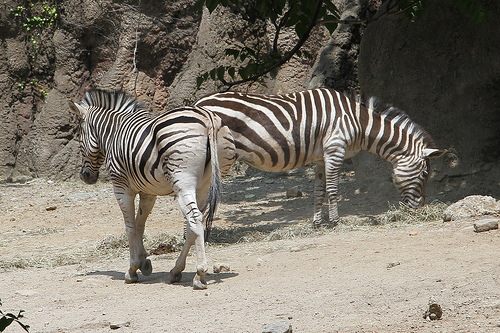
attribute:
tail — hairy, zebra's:
[181, 106, 239, 253]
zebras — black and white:
[193, 87, 445, 231]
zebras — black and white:
[73, 87, 237, 289]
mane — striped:
[352, 89, 435, 149]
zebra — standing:
[66, 85, 226, 287]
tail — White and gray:
[206, 114, 221, 238]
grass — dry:
[373, 199, 451, 225]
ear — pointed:
[420, 147, 450, 158]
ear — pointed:
[70, 100, 85, 115]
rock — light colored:
[253, 310, 301, 332]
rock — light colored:
[105, 310, 132, 329]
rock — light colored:
[463, 208, 498, 233]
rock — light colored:
[442, 189, 497, 213]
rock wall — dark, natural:
[38, 11, 358, 99]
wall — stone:
[3, 1, 496, 176]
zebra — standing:
[191, 86, 449, 230]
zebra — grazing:
[182, 87, 442, 245]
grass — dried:
[392, 194, 442, 219]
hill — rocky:
[7, 175, 499, 330]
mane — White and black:
[80, 87, 136, 112]